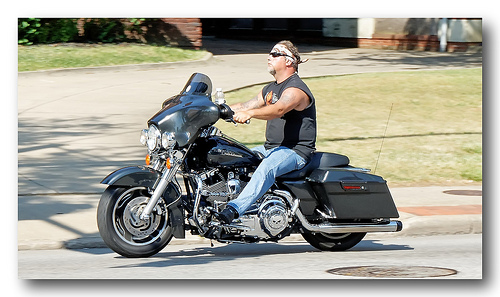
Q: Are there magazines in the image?
A: No, there are no magazines.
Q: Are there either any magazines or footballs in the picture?
A: No, there are no magazines or footballs.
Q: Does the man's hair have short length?
A: Yes, the hair is short.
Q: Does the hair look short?
A: Yes, the hair is short.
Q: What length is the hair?
A: The hair is short.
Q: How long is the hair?
A: The hair is short.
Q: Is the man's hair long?
A: No, the hair is short.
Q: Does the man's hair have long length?
A: No, the hair is short.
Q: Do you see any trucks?
A: No, there are no trucks.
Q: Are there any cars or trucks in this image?
A: No, there are no trucks or cars.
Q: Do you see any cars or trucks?
A: No, there are no trucks or cars.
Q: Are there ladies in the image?
A: No, there are no ladies.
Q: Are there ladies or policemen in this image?
A: No, there are no ladies or policemen.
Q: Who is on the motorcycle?
A: The man is on the motorcycle.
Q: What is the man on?
A: The man is on the motorcycle.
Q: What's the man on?
A: The man is on the motorcycle.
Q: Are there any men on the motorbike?
A: Yes, there is a man on the motorbike.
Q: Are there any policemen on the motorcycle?
A: No, there is a man on the motorcycle.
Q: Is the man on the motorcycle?
A: Yes, the man is on the motorcycle.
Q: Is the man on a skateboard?
A: No, the man is on the motorcycle.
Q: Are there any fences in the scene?
A: No, there are no fences.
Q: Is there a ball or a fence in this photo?
A: No, there are no fences or balls.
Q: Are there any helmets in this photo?
A: No, there are no helmets.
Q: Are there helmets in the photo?
A: No, there are no helmets.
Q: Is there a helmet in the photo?
A: No, there are no helmets.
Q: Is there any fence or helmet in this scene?
A: No, there are no helmets or fences.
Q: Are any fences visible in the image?
A: No, there are no fences.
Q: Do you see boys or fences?
A: No, there are no fences or boys.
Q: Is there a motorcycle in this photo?
A: Yes, there is a motorcycle.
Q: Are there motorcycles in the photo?
A: Yes, there is a motorcycle.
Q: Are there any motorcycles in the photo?
A: Yes, there is a motorcycle.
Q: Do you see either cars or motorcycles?
A: Yes, there is a motorcycle.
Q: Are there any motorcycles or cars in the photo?
A: Yes, there is a motorcycle.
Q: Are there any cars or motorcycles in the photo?
A: Yes, there is a motorcycle.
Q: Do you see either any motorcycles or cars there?
A: Yes, there is a motorcycle.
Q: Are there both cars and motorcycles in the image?
A: No, there is a motorcycle but no cars.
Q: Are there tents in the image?
A: No, there are no tents.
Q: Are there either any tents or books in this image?
A: No, there are no tents or books.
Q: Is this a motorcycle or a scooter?
A: This is a motorcycle.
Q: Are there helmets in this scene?
A: No, there are no helmets.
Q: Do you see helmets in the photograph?
A: No, there are no helmets.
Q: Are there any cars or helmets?
A: No, there are no helmets or cars.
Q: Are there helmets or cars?
A: No, there are no helmets or cars.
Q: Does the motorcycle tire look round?
A: Yes, the tire is round.